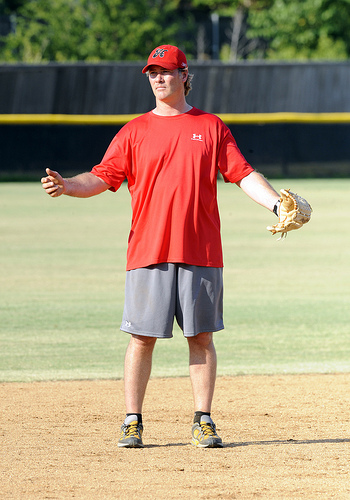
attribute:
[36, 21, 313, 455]
man — blonde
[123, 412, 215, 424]
socks — black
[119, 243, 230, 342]
shorts — gray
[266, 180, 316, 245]
glove — brown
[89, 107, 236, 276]
shirt — red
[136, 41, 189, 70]
cap — red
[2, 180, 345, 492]
field — green